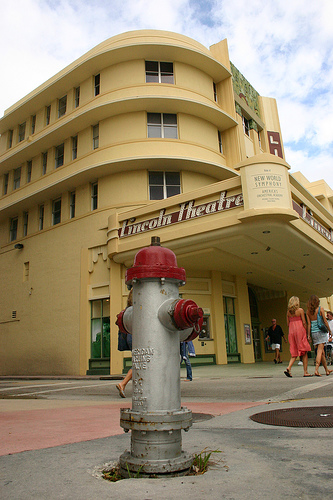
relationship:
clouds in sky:
[21, 13, 80, 48] [229, 7, 329, 150]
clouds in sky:
[0, 0, 332, 188] [3, 0, 332, 187]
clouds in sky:
[222, 7, 325, 86] [3, 0, 332, 187]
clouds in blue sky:
[0, 0, 332, 188] [0, 0, 331, 189]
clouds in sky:
[260, 22, 295, 46] [196, 3, 209, 18]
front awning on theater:
[107, 152, 332, 302] [14, 34, 316, 380]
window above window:
[144, 167, 186, 199] [143, 108, 180, 139]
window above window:
[143, 108, 180, 139] [141, 56, 179, 85]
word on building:
[114, 188, 247, 237] [15, 20, 308, 385]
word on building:
[173, 192, 241, 216] [9, 30, 332, 364]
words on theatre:
[115, 188, 247, 239] [5, 27, 322, 372]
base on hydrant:
[97, 417, 224, 483] [111, 230, 209, 473]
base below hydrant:
[97, 417, 224, 483] [111, 230, 209, 473]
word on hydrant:
[127, 343, 156, 373] [114, 275, 188, 417]